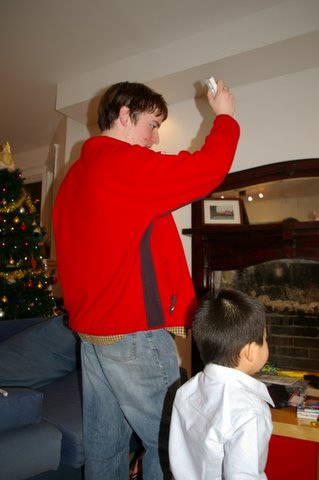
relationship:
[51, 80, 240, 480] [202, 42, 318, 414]
man playing a video game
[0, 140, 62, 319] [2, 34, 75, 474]
christmas tree in background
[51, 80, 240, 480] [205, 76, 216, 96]
man plays controller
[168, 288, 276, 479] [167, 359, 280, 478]
boy in collared shirt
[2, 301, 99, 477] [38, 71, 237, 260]
couch next to man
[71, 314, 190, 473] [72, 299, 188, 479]
jeans on legs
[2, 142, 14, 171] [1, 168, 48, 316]
angel on tree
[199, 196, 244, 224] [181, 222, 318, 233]
picture frame on shelf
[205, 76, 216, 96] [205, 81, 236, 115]
controller in hand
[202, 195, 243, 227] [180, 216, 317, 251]
picture on mantlepiece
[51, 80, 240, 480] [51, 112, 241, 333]
man wearing jacket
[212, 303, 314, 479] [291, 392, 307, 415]
table with items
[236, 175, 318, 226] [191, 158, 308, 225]
mirror in mantelpiece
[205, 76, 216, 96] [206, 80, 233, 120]
controller in hand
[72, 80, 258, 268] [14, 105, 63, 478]
man standing in livingroom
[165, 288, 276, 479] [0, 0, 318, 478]
boy standing in room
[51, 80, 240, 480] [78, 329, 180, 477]
man wearing jeans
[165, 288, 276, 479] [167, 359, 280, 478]
boy wearing collared shirt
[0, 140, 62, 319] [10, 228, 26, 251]
christmas tree has ornaments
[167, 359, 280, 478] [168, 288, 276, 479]
collared shirt on boy